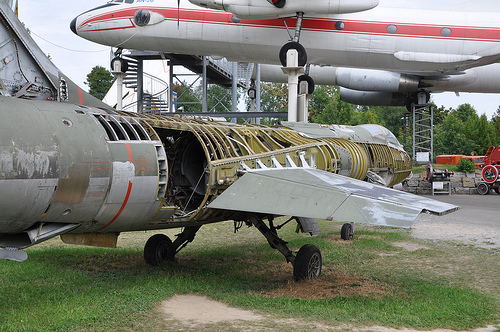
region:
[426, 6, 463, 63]
window of airplane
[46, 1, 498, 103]
airplane with red stripe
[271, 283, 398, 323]
patch of dead grass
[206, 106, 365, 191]
skeleton of airplane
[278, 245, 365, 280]
the tire of airplane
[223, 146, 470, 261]
the wing of the airplane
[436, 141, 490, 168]
orange truck in background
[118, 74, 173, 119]
a spiral staircase in the background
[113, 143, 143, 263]
an orange stripe on airplane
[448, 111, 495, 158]
a tree in the background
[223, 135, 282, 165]
The shell of the plane.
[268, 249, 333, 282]
The wheels are black.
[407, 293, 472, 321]
The grass is green.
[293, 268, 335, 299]
Dry spot of grass.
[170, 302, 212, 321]
Bald spot on the ground.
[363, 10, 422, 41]
Windows of the plane.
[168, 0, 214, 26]
Red line on the plane.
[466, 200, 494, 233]
The ground is paved.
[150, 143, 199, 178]
Inside of the plane.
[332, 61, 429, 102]
The plane's engine.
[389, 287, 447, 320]
part of some grass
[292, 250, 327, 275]
right wheel of the plane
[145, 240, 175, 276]
left wheel of the plane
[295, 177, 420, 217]
right wing of the plane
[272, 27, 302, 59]
wheel of a plane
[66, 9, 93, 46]
front tip of a plane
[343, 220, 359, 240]
front wheel of plane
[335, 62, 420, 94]
left engine of a plane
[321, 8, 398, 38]
part of some windows on the plane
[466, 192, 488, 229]
part of the road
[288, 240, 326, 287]
black rubber tire plane wheel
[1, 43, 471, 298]
a significantly damaged airplane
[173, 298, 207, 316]
a patch of dirt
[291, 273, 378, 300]
dead brown grass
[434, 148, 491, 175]
a large orange truck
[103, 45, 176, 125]
spiral staircase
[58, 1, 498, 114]
a large airplane is jacked up in the air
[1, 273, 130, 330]
a patch of green grass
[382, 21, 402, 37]
window to passenger airplane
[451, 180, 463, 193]
concrete wall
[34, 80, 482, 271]
Plane is broken down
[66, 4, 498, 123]
Red and white plane is in the background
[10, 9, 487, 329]
Photo was taken in the daytime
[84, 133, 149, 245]
Thin Red circular line is around the plant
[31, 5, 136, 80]
Sky is powder blue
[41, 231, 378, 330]
Plane is parked in grass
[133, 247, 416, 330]
Grass is green with two bare patches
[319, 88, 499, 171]
Trees are in the background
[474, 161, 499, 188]
A red wheel is in the background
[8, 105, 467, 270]
Broken plane is light gray in color